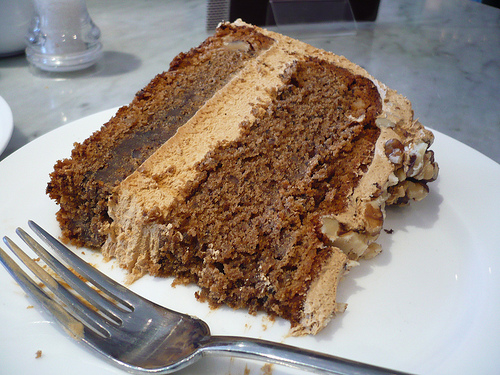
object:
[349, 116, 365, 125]
nuts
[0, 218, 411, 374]
fork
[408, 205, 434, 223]
shadow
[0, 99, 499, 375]
saucer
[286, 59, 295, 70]
icing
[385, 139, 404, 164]
nuts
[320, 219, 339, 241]
nuts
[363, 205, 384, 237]
nuts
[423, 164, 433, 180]
nuts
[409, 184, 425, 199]
nuts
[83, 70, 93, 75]
shadow counter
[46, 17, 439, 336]
cake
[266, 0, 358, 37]
document holder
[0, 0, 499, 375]
table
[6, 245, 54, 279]
cake smudge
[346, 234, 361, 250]
walnut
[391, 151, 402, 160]
walnut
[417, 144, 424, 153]
walnut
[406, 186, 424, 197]
walnut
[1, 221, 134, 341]
prong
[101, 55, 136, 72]
shadow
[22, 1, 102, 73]
container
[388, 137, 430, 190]
frosting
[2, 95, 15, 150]
edge